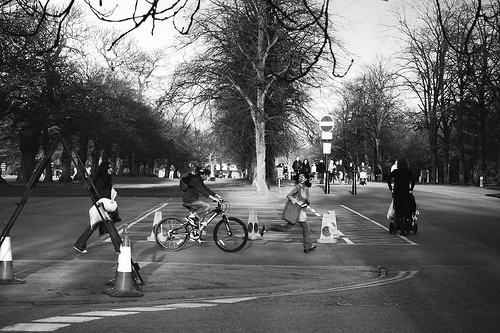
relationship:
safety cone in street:
[0, 232, 30, 282] [20, 236, 110, 325]